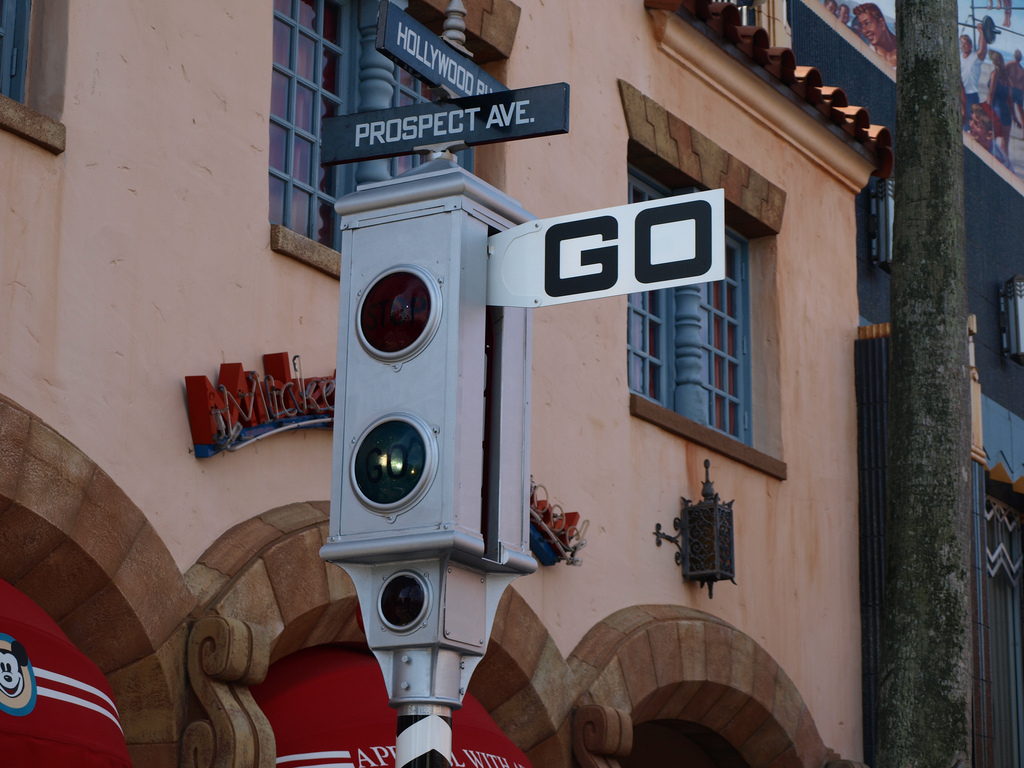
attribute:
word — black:
[546, 197, 712, 297]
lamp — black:
[671, 480, 741, 597]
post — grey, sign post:
[320, 162, 558, 763]